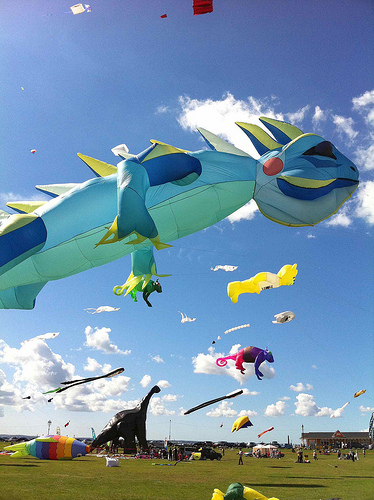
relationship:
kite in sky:
[201, 321, 266, 336] [5, 9, 357, 369]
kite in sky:
[215, 344, 275, 380] [0, 1, 372, 444]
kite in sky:
[224, 261, 300, 303] [0, 1, 372, 444]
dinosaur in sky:
[0, 115, 360, 312] [0, 1, 372, 444]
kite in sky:
[348, 387, 366, 408] [0, 1, 372, 444]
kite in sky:
[192, 259, 251, 278] [0, 1, 372, 444]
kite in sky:
[340, 375, 373, 411] [2, 6, 373, 141]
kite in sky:
[55, 0, 99, 22] [9, 26, 366, 110]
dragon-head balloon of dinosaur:
[234, 116, 360, 228] [0, 115, 360, 312]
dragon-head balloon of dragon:
[234, 116, 360, 228] [208, 75, 366, 248]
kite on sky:
[20, 365, 124, 401] [299, 230, 370, 387]